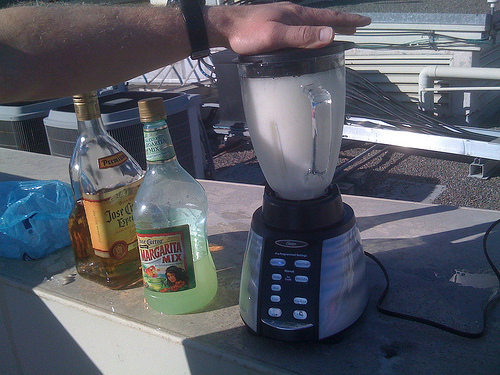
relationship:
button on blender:
[288, 259, 311, 274] [222, 43, 391, 348]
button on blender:
[271, 284, 283, 292] [231, 39, 374, 350]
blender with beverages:
[222, 43, 391, 348] [237, 66, 348, 201]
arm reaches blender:
[1, 0, 374, 104] [222, 43, 391, 348]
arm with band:
[1, 0, 374, 104] [180, 0, 212, 61]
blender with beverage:
[222, 43, 391, 348] [57, 92, 139, 288]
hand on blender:
[220, 3, 377, 53] [222, 43, 391, 348]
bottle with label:
[124, 90, 220, 315] [130, 222, 203, 293]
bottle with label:
[39, 79, 139, 289] [74, 187, 139, 263]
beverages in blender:
[237, 66, 348, 201] [222, 43, 391, 348]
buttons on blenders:
[259, 249, 322, 327] [219, 41, 383, 344]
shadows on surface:
[365, 202, 481, 265] [212, 208, 498, 369]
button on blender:
[270, 255, 284, 266] [231, 39, 374, 350]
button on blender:
[294, 260, 311, 269] [222, 43, 391, 348]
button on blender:
[270, 272, 284, 281] [222, 43, 391, 348]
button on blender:
[270, 284, 284, 293] [231, 39, 374, 350]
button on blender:
[272, 293, 284, 301] [218, 39, 377, 345]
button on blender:
[289, 294, 312, 305] [231, 39, 374, 350]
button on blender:
[269, 306, 281, 318] [231, 39, 374, 350]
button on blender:
[290, 306, 311, 326] [231, 39, 374, 350]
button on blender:
[291, 309, 307, 321] [231, 39, 374, 350]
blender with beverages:
[239, 188, 369, 350] [237, 66, 348, 201]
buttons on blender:
[259, 249, 322, 327] [231, 39, 374, 350]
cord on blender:
[373, 219, 484, 342] [231, 39, 374, 350]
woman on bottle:
[164, 266, 185, 288] [135, 96, 217, 316]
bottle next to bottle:
[66, 88, 145, 290] [131, 95, 219, 316]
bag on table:
[8, 181, 79, 262] [9, 152, 478, 372]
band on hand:
[180, 0, 212, 61] [178, 5, 364, 52]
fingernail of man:
[320, 24, 331, 40] [3, 1, 371, 98]